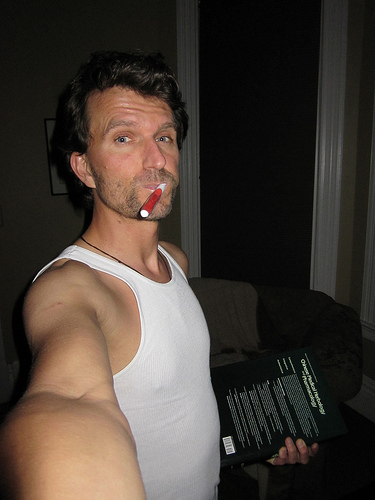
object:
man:
[5, 47, 221, 498]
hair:
[50, 48, 187, 205]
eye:
[113, 134, 132, 144]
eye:
[155, 134, 173, 143]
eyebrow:
[101, 120, 137, 135]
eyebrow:
[155, 120, 174, 133]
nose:
[143, 138, 166, 170]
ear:
[71, 149, 94, 189]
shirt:
[34, 246, 222, 499]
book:
[210, 342, 345, 459]